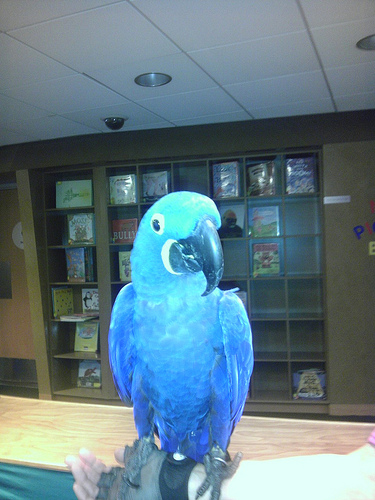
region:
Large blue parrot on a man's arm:
[109, 190, 256, 499]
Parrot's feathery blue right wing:
[107, 281, 135, 404]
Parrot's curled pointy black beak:
[177, 220, 225, 295]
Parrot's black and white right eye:
[150, 213, 166, 236]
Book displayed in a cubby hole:
[54, 178, 93, 207]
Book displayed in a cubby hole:
[107, 175, 138, 203]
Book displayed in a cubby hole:
[65, 212, 97, 244]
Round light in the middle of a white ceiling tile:
[132, 72, 175, 89]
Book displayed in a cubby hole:
[249, 242, 282, 276]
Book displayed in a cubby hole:
[290, 368, 326, 400]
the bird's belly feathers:
[148, 318, 195, 382]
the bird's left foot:
[187, 431, 245, 498]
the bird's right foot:
[113, 416, 164, 489]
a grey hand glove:
[75, 445, 196, 499]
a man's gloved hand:
[64, 423, 200, 498]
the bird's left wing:
[218, 279, 261, 445]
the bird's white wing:
[113, 270, 159, 423]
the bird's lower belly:
[160, 383, 195, 450]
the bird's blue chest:
[147, 296, 207, 353]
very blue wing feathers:
[216, 293, 260, 433]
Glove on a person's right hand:
[91, 439, 157, 498]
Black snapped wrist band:
[159, 446, 195, 497]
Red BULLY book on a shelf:
[113, 216, 139, 244]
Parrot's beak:
[183, 218, 226, 297]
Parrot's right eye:
[150, 217, 162, 231]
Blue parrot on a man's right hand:
[101, 189, 255, 499]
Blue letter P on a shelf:
[350, 218, 365, 244]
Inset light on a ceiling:
[126, 68, 179, 89]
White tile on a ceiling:
[8, 0, 197, 58]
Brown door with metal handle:
[2, 170, 41, 388]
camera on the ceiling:
[105, 106, 135, 132]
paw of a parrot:
[188, 448, 243, 498]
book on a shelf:
[271, 355, 325, 419]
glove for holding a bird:
[73, 449, 198, 497]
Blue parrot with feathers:
[74, 183, 233, 416]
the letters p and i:
[341, 218, 370, 245]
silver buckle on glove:
[105, 447, 196, 494]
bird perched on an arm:
[115, 191, 245, 499]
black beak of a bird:
[194, 229, 227, 309]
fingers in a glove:
[54, 435, 145, 497]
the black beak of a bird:
[175, 216, 228, 295]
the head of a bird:
[126, 186, 231, 292]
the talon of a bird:
[184, 439, 245, 498]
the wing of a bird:
[216, 288, 258, 438]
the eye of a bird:
[147, 206, 168, 235]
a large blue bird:
[103, 188, 256, 498]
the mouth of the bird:
[174, 237, 200, 268]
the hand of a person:
[60, 433, 199, 498]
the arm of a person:
[200, 425, 373, 498]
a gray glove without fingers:
[89, 438, 196, 499]